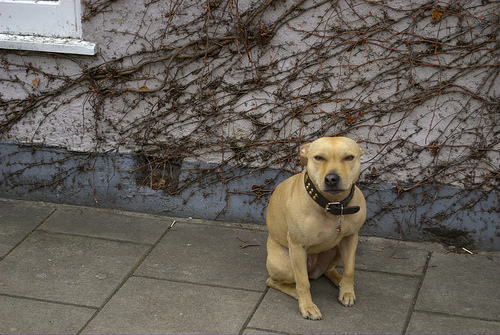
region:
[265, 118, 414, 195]
the head of a dog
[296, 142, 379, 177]
the eyes of a dog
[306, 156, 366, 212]
the nose of a dog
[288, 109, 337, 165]
the ear of a dog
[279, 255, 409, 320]
the paws of a dog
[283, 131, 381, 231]
a dog wearing a collar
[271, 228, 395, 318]
the legs of a dog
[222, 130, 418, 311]
the body of a dog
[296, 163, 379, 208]
the mouth of a dog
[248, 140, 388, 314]
a little brown dog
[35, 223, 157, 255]
Small line of the walk way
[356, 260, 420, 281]
Small line of the walk way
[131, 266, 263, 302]
Small line of the walk way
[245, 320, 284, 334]
Small line of the walk way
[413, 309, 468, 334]
Small line of the walk way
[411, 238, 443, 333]
Small line of the walk way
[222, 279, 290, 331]
Small line of the walk way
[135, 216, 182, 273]
Small line of the walk way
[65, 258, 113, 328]
Small line of the walk way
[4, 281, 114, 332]
Small line of the walk way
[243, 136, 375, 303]
dog on the sidewalk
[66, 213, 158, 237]
cement tile on sidewalk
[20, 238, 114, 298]
cement tile on sidewalk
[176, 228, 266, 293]
cement tile on sidewalk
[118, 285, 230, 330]
cement tile on sidewalk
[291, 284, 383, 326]
cement tile on sidewalk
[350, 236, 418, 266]
cement tile on sidewalk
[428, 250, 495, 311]
cement tile on sidewalk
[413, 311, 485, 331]
cement tile on sidewalk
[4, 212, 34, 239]
cement tile on sidewalk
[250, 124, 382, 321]
a dog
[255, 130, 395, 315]
the dog is sitting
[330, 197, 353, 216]
a collar on the dog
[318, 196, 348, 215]
the collar is brown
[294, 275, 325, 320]
the dogs right leg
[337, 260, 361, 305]
the dogs left leg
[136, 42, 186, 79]
tree branch on the wall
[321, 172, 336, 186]
the dogs nose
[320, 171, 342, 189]
nose is black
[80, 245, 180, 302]
the ground is grey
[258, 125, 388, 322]
the dog is sitting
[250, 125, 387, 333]
the dog is beige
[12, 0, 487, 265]
the wall behind the dog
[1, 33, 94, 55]
the window sill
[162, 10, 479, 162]
vines growing on the wall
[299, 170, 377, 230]
collar on the dog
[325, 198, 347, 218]
buckle of the collar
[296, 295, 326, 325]
paw of the dog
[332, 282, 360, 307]
paw of the dog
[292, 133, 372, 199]
the head of the dog